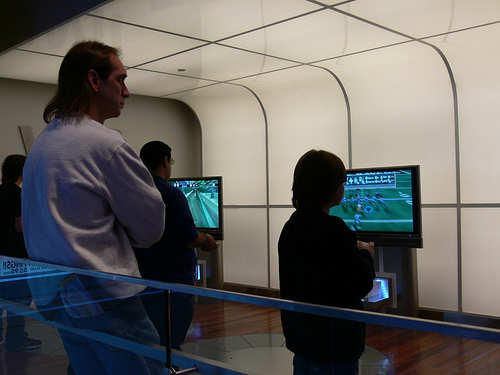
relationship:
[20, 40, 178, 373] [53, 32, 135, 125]
man has head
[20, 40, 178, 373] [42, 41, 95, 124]
man has hair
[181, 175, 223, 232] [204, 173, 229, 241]
screen has frame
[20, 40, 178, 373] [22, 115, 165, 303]
man wears shirt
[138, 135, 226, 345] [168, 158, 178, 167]
man wearing glasses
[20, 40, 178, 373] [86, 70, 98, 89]
man has ear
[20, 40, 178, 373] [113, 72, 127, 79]
man has eyebrow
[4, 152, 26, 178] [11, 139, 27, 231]
hair of man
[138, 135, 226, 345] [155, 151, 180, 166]
man wearing glasses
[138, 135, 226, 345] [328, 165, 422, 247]
man watching screen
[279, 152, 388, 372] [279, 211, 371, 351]
boy wearing shirt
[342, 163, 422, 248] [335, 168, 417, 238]
frame surrounding screen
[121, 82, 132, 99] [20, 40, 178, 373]
nose of man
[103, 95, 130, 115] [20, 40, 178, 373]
mouth of man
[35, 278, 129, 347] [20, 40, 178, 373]
pockets of man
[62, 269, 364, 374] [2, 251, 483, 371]
top with railings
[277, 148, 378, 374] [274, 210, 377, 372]
boy wearing outfit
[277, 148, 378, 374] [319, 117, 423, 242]
boy looking at monitor